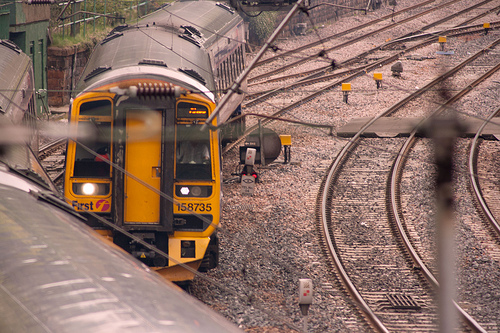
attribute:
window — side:
[211, 46, 243, 91]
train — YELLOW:
[65, 3, 264, 263]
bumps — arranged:
[276, 132, 302, 164]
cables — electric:
[228, 40, 387, 106]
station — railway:
[40, 43, 461, 276]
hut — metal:
[21, 21, 60, 84]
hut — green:
[0, 0, 52, 112]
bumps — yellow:
[340, 80, 357, 107]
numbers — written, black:
[175, 201, 212, 213]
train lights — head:
[78, 177, 207, 200]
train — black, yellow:
[55, 0, 250, 295]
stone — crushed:
[238, 50, 498, 333]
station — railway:
[0, 2, 324, 329]